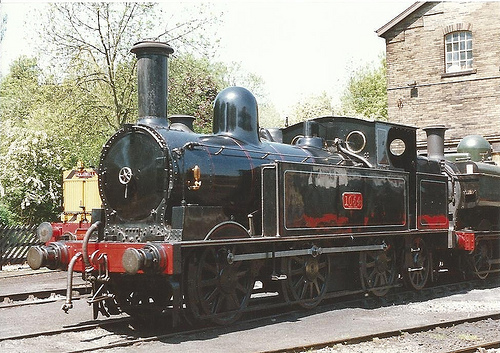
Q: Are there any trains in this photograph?
A: Yes, there is a train.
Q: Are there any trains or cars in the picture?
A: Yes, there is a train.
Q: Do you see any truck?
A: No, there are no trucks.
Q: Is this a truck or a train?
A: This is a train.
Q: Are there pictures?
A: No, there are no pictures.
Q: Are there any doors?
A: Yes, there is a door.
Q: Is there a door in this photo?
A: Yes, there is a door.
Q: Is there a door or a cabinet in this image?
A: Yes, there is a door.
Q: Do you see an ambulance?
A: No, there are no ambulances.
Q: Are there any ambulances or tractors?
A: No, there are no ambulances or tractors.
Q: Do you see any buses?
A: No, there are no buses.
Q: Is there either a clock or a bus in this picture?
A: No, there are no buses or clocks.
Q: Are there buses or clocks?
A: No, there are no buses or clocks.